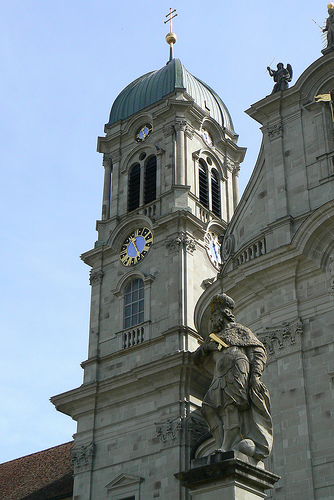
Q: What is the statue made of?
A: Stone.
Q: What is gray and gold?
A: The statue.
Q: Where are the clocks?
A: On the tower.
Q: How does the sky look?
A: Clear and blue.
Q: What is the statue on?
A: A pole.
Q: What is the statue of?
A: A man.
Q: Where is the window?
A: Under the clock.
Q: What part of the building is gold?
A: The clock.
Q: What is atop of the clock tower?
A: A metal rod.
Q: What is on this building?
A: A clock.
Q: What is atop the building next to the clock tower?
A: Angel statue.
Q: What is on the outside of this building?
A: A clock.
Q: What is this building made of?
A: Bricks.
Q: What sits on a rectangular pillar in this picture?
A: A statue of a man.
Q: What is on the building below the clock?
A: A window.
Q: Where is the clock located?
A: On the outside of the building.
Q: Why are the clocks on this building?
A: So people can tell the time.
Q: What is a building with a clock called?
A: A clock tower.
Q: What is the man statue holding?
A: An gold strap.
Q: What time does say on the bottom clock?
A: 10:25.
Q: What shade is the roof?
A: Green.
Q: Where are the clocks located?
A: On the front of the building.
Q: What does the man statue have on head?
A: Crown hat.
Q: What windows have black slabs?
A: Front top and side.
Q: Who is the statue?
A: A saint.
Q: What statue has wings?
A: Gargyole.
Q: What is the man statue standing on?
A: Granite post.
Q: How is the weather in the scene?
A: Calm and dry.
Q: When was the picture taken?
A: 10:25.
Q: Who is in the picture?
A: No one.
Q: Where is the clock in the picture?
A: On left above window.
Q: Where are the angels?
A: On the roof of the church.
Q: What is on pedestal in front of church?
A: A statue of a man with gold sword.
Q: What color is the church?
A: Gray.